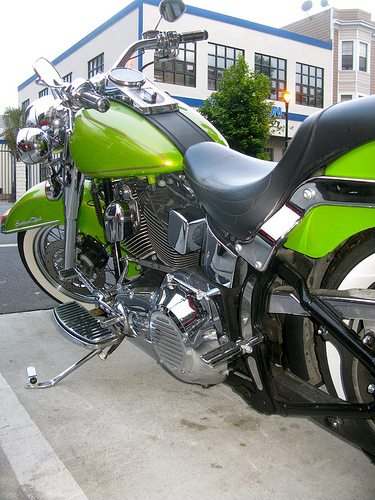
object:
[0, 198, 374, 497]
parking lot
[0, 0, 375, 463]
motorcycle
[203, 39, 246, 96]
windows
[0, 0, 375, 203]
building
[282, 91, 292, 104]
light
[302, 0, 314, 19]
satellite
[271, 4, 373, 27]
roof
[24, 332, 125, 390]
kickstand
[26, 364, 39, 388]
bolt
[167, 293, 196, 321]
reflection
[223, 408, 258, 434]
grease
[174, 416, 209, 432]
grease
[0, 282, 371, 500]
pavement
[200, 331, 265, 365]
foot holder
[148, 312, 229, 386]
grate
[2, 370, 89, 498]
white strip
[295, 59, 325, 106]
windows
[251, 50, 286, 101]
windows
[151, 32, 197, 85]
windows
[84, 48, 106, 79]
windows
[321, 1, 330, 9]
satellite